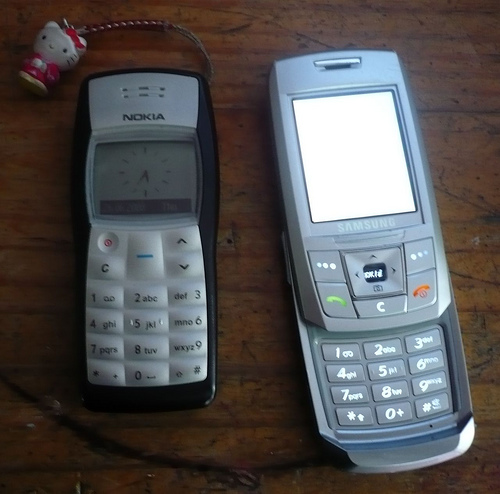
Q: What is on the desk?
A: Two phones.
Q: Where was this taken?
A: In a room.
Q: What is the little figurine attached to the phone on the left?
A: Hello Kitty.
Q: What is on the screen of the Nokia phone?
A: A clock.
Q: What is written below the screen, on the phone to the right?
A: Samsung.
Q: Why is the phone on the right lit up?
A: It is turning on.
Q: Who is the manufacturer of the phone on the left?
A: Nokia.